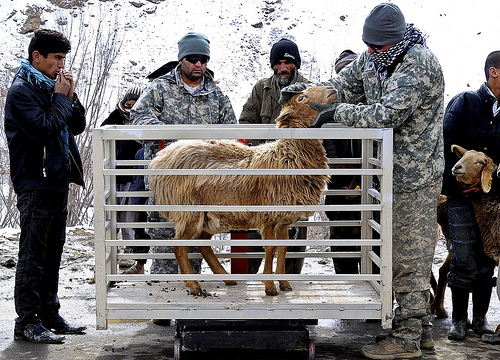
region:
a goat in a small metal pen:
[92, 84, 394, 329]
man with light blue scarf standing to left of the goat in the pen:
[4, 27, 86, 344]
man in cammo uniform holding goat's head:
[282, 0, 444, 358]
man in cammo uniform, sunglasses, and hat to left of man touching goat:
[128, 32, 234, 274]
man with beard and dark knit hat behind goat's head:
[242, 37, 318, 122]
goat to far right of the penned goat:
[449, 144, 499, 266]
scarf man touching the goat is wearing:
[369, 22, 429, 65]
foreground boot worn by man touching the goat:
[357, 292, 428, 358]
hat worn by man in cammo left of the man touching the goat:
[177, 31, 212, 60]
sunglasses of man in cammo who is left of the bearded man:
[185, 53, 210, 64]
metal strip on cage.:
[199, 269, 295, 281]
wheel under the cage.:
[163, 333, 185, 356]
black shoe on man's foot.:
[18, 326, 59, 348]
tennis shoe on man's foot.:
[357, 340, 416, 355]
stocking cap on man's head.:
[365, 8, 397, 41]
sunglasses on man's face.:
[185, 58, 210, 63]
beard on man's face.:
[267, 72, 295, 87]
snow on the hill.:
[157, 8, 216, 23]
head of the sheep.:
[451, 147, 494, 191]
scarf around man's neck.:
[21, 65, 50, 92]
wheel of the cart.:
[170, 336, 184, 353]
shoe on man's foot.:
[365, 341, 400, 356]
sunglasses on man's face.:
[187, 55, 206, 61]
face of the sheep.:
[292, 87, 334, 114]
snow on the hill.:
[147, 16, 184, 31]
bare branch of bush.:
[100, 34, 115, 86]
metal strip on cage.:
[225, 271, 319, 283]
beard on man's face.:
[272, 74, 292, 84]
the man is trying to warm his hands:
[37, 48, 89, 95]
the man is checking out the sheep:
[273, 38, 418, 130]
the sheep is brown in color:
[211, 149, 282, 196]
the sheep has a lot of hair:
[211, 154, 271, 192]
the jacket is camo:
[383, 82, 425, 124]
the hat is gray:
[366, 0, 398, 38]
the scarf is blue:
[22, 57, 47, 89]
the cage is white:
[167, 123, 283, 227]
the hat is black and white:
[268, 35, 301, 70]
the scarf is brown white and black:
[116, 100, 133, 116]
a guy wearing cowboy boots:
[3, 25, 88, 347]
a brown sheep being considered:
[134, 72, 359, 298]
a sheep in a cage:
[80, 57, 405, 342]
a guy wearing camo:
[309, 0, 447, 358]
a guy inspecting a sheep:
[90, 17, 465, 352]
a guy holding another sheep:
[441, 38, 499, 328]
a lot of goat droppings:
[100, 261, 236, 321]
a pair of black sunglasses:
[181, 51, 214, 66]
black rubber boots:
[432, 260, 499, 350]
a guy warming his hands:
[4, 28, 94, 349]